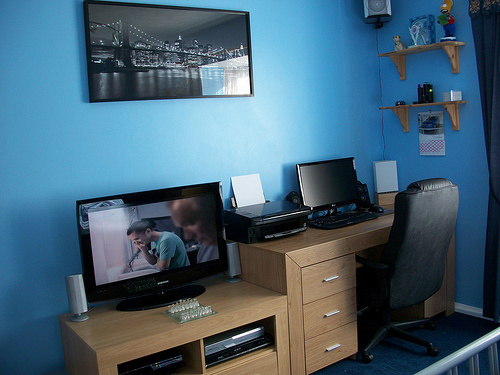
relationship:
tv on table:
[75, 180, 230, 315] [59, 278, 291, 374]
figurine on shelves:
[437, 0, 457, 43] [373, 39, 464, 133]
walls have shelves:
[0, 0, 485, 374] [373, 39, 464, 133]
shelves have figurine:
[373, 39, 464, 133] [439, 0, 458, 43]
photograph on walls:
[84, 1, 255, 103] [0, 0, 485, 374]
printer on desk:
[226, 196, 312, 243] [240, 205, 458, 373]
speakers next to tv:
[66, 240, 242, 323] [75, 180, 230, 315]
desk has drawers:
[240, 205, 458, 373] [300, 252, 362, 374]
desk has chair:
[240, 205, 458, 373] [358, 178, 460, 365]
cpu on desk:
[297, 157, 384, 232] [240, 205, 458, 373]